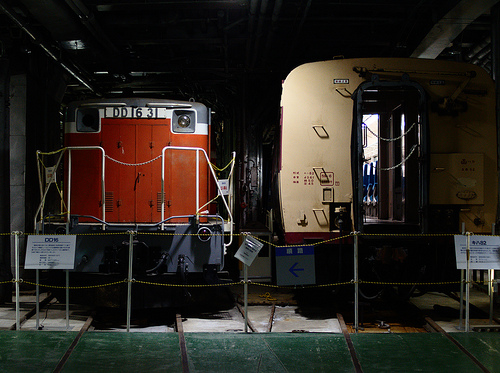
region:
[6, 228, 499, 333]
a chain railing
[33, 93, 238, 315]
a train display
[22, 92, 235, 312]
1 dd 16 31 located on the front of a train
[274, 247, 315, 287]
arrow pointing to the left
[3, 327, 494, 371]
green flooring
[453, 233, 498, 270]
white sign with black writing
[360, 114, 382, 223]
illuminated lights inside the room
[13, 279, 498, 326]
train tracks on display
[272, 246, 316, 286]
square gray sign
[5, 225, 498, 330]
metal posts hooked to chains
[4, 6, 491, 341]
two trains on display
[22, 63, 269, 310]
the train on the left is red and grey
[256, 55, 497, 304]
the train on the right is beige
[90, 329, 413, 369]
the floor is green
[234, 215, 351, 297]
the arrow is pointing left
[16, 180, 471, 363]
the trains are on tracks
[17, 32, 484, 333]
the trains are not moving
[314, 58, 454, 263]
the door is open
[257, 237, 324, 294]
the arrow is blue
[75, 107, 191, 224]
the doors are closed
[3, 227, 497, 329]
thin gray metal fencing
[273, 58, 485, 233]
partially shaded tan colored train front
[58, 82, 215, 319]
front of red and black train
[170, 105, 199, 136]
one round dark train headlight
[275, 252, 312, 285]
one blue left arrow on gray background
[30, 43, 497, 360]
two non-working trains inside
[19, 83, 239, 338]
one train behind fence with sign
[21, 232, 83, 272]
rectangular shaped sign with blue lettering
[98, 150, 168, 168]
length of gray metal chain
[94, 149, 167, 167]
chain suspended between metal posts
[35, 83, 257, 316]
train on a track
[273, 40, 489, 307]
train on a track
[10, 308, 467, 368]
tracks train are on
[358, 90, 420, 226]
doorway to a train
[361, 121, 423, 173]
chain blocking doorway to train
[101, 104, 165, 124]
letters and number on train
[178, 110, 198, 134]
light on a train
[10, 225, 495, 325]
chains blocking the train area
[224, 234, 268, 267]
paper hanging from chain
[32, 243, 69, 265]
lettering on the paper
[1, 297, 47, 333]
small old metal rail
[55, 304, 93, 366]
small old metal rail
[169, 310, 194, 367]
small old metal rail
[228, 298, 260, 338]
small old metal rail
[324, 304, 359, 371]
small old metal rail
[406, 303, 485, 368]
small old metal rail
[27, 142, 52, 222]
small old metal rail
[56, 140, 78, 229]
small old metal rail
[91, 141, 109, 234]
small old metal rail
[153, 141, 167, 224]
small old metal rail